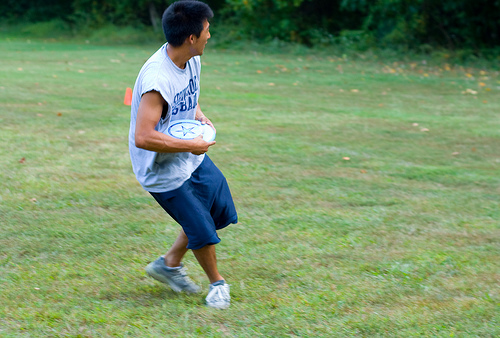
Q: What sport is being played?
A: Frisbee.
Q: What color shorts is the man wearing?
A: Blue.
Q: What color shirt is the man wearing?
A: Grey.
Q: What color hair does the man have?
A: Black.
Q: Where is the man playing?
A: On the grass.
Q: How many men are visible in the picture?
A: 1.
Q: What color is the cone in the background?
A: Orange.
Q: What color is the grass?
A: Green.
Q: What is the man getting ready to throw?
A: A frisbee.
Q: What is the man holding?
A: Frisbee.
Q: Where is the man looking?
A: Away from the camera.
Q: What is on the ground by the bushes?
A: Leaves.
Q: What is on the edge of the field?
A: Bushes.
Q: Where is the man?
A: In a field.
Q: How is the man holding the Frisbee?
A: Like he's about to throw.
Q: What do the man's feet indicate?
A: He's running.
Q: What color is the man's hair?
A: Black.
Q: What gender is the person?
A: Male.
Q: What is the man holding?
A: Frisbee.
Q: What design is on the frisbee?
A: Star.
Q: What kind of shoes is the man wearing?
A: Sneakers.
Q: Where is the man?
A: On a field.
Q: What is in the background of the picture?
A: Trees.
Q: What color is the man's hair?
A: Black.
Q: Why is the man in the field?
A: To play frisbee.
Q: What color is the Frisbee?
A: White.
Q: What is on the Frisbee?
A: A star.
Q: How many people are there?
A: One.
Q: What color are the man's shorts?
A: Blue.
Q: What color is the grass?
A: Green.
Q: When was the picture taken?
A: Daytime.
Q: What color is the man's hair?
A: Black.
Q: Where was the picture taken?
A: In a park.